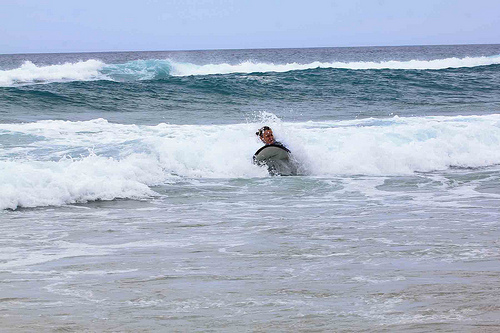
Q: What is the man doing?
A: Boogie boarding.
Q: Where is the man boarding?
A: In the ocean.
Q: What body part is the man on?
A: His chest and stomach.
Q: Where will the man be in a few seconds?
A: On the sand.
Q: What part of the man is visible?
A: His head.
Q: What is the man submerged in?
A: Water.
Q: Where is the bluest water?
A: Just behind the man in the next wave.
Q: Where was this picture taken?
A: An ocean.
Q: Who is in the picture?
A: A man.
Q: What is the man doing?
A: Surfing.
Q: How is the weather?
A: Clear.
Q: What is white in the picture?
A: The waves.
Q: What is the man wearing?
A: A wetsuit.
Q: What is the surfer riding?
A: A wave.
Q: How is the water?
A: Choppy.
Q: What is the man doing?
A: Surfing.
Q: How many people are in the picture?
A: One.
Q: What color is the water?
A: Blue.